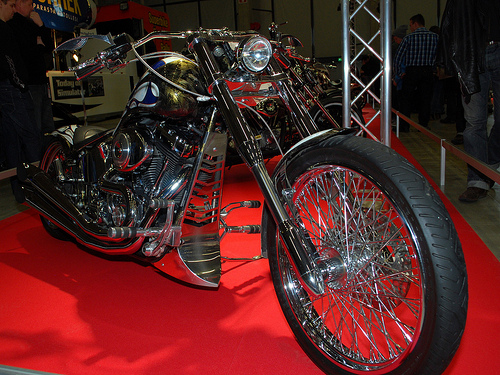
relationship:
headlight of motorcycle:
[240, 36, 271, 71] [12, 19, 466, 373]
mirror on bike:
[47, 31, 92, 64] [13, 19, 466, 372]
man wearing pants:
[442, 0, 500, 208] [455, 73, 498, 189]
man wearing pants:
[393, 12, 437, 130] [404, 67, 439, 147]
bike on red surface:
[13, 19, 466, 372] [29, 274, 162, 358]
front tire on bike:
[266, 133, 468, 373] [13, 19, 466, 372]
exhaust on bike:
[12, 162, 159, 259] [13, 19, 466, 372]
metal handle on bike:
[54, 29, 189, 80] [13, 19, 466, 372]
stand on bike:
[107, 224, 169, 241] [13, 19, 466, 372]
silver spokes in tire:
[295, 179, 400, 349] [245, 129, 485, 371]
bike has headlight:
[13, 19, 466, 372] [235, 30, 275, 75]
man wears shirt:
[405, 16, 493, 94] [398, 31, 456, 89]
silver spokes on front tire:
[295, 179, 400, 349] [266, 133, 468, 373]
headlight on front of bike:
[240, 36, 271, 71] [48, 27, 372, 267]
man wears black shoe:
[442, 0, 500, 208] [460, 182, 490, 204]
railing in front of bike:
[393, 113, 494, 185] [13, 19, 466, 372]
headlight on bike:
[240, 36, 271, 71] [13, 19, 466, 372]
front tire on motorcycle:
[266, 133, 468, 373] [12, 19, 466, 373]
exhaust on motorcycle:
[12, 162, 159, 259] [12, 19, 466, 373]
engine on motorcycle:
[83, 112, 200, 229] [12, 19, 466, 373]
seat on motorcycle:
[73, 120, 122, 141] [12, 19, 466, 373]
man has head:
[393, 12, 443, 140] [408, 13, 426, 31]